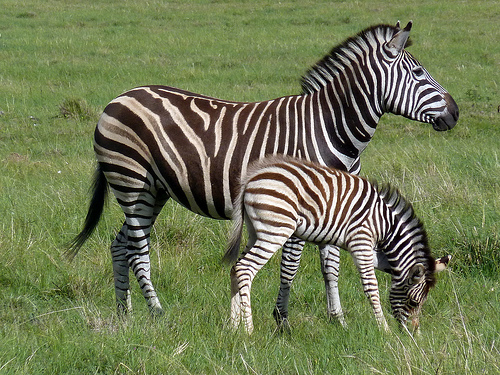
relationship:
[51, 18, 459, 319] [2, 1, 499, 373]
zebra standing on grass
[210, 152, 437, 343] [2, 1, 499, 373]
zebra eating grass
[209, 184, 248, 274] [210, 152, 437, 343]
tail on zebra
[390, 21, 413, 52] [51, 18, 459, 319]
ear on zebra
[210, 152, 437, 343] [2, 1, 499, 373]
zebra looking at grass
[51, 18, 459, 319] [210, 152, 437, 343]
zebra next to zebra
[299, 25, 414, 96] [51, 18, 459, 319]
mane on zebra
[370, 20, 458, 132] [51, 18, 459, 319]
head of zebra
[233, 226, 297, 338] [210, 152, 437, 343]
leg of zebra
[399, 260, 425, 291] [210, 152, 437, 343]
ear of zebra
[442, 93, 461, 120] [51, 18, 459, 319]
nose on zebra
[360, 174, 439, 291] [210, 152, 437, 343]
mane on zebra